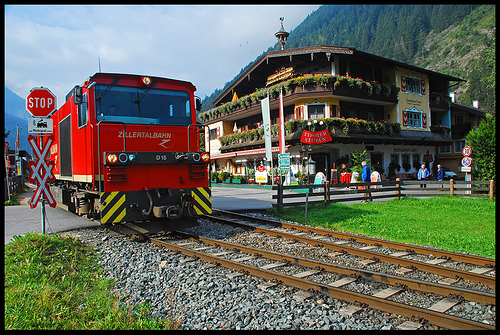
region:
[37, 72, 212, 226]
a bright red train car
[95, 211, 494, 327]
grey stones surrounding railroad tracks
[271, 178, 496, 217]
low wooden fence bordering grassy area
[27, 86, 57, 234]
sign cautioning people to stop at railroad crossing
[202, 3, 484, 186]
large building in front of wooded hill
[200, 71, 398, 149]
flowering plants set above railing of building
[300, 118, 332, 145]
red banner with three lights above it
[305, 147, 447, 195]
people walking near building's entrance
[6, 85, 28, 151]
small visible sections of blue mountains in the distance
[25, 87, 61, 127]
a stop sign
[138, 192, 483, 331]
brown rail road tracks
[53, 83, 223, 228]
a red train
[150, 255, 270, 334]
rocks next to the tracks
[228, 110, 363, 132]
flowers on the building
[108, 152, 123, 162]
a light on the train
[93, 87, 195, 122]
the windshield of the train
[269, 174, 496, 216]
brown wooden fence near train tracks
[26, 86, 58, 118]
red and white octagonal stop sign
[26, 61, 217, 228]
red train on train tracks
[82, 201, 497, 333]
brown metal train tracks near building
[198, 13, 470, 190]
brown and white square building near train tracks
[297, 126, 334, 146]
curved red sign on building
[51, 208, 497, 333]
bed of gray rocks under train tracks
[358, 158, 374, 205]
man walking near fence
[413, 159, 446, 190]
people walking near fence and building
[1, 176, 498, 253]
paved gray concrete street near train tracks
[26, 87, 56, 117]
red stop sign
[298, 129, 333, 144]
red sign above the door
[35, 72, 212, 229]
red train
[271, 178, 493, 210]
brown wooden fence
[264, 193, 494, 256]
section of bright green grass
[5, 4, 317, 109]
section of a blue sky with clouds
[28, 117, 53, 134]
white and black sign under the stop sign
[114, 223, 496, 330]
train tracks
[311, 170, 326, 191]
sandwich board in front of the building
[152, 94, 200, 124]
window of a train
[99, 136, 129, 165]
lights of a train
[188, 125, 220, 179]
light of a train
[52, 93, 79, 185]
door of a train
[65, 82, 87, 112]
side view mirror of a train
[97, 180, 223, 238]
bumper of a train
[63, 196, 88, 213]
wheel of a train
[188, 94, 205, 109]
side mirror of a train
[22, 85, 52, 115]
white letters on a red traffic stop sign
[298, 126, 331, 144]
red banner with gold letters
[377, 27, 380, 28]
A green leaf on a plant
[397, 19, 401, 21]
A green leaf on a plant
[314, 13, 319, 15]
A green leaf on a plant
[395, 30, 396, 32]
A green leaf on a plant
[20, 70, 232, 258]
train on the tracks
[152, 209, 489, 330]
a set of tracks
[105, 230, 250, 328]
gravel on the ground